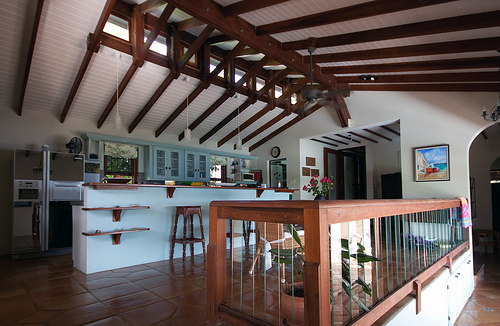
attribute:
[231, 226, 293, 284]
railing — brown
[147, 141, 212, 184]
cupboard doors — white, glass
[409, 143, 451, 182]
picture — boat, water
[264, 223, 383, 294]
plant — terra cotta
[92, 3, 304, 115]
lights — sky, wooden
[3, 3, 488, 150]
frames — thick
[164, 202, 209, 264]
stool — wooden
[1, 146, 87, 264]
refrigerator — stainless steel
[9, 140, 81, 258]
refrigerator — silver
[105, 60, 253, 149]
lights — white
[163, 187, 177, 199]
wedge — wooden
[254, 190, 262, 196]
wedge — wooden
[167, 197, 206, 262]
stool — brown 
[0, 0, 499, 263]
wall — white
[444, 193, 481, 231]
towel — colored 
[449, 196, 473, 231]
towel — orange, red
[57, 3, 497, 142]
beams — wood 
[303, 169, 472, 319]
divider — wood 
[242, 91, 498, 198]
wall — white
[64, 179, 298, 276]
island — white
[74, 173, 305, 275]
kitchen island — white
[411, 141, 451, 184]
painting — colorful